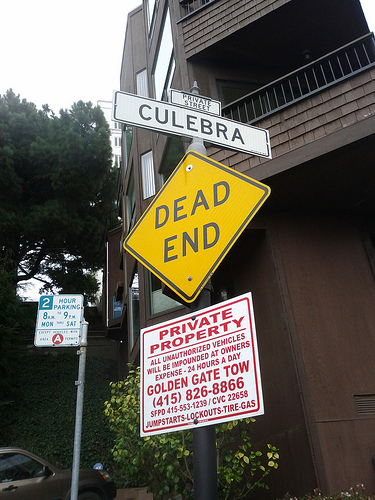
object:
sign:
[135, 288, 269, 443]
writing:
[146, 383, 156, 396]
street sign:
[108, 82, 275, 164]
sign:
[33, 291, 86, 350]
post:
[60, 345, 89, 498]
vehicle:
[0, 442, 119, 499]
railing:
[219, 30, 374, 135]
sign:
[117, 148, 274, 308]